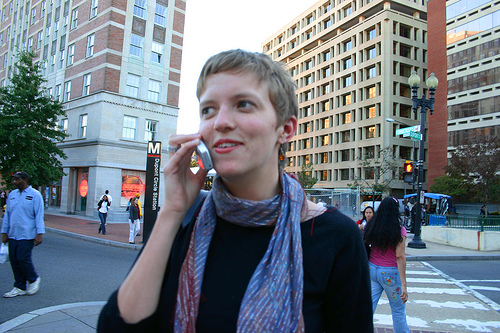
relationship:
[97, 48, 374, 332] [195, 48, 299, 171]
girl has hair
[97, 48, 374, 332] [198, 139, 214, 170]
girl on phone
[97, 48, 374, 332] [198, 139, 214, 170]
girl using phone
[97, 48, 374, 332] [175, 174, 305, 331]
girl wearing scarf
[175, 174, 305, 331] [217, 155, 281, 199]
scarf around neck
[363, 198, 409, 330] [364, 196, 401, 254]
woman has hair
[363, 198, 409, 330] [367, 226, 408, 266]
woman has shirt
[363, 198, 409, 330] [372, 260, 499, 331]
woman in crosswalk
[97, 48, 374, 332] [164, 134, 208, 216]
girl has hand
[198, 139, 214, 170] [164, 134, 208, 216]
phone in hand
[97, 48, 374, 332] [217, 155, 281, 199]
girl has neck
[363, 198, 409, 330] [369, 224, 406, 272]
woman wearing pink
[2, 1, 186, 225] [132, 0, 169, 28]
building has windows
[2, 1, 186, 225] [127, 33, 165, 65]
building has windows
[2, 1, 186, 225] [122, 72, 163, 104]
building has windows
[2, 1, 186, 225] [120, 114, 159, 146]
building has windows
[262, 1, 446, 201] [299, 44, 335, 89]
building has windows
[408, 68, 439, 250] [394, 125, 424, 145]
street light has signs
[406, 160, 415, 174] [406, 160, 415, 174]
don't walk says don't walk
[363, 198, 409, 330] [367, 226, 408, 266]
woman wearing shirt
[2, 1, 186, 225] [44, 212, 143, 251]
building on corner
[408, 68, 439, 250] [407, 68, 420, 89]
street light has globe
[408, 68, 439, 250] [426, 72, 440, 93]
street light has globe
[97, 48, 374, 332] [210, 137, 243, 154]
girl wearing lipstick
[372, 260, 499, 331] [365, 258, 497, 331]
crosswalk in street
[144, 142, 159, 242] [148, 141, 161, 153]
pole has m